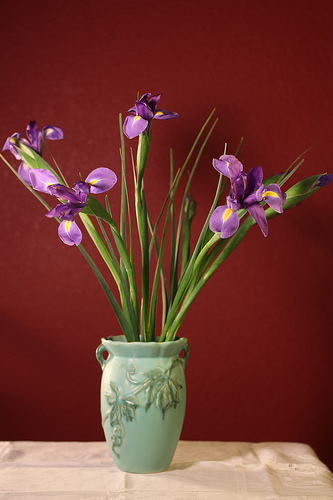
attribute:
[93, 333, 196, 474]
vase — green, light green, porcelain, decorative, blue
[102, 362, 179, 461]
design — leaf, leaves, green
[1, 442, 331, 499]
table cloth — tan, brown, white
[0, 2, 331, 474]
wall — red, burgundy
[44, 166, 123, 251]
flower bloom — purple, fully bloomed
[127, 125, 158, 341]
flower stem — green, long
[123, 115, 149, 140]
flower petal — purple, yellow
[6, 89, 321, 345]
bouquet — purple flowers, of flowers, of purple flowers, on display, flowers, purple, yellow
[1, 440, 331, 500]
table — white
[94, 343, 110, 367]
handle — green, small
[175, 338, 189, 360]
handle — small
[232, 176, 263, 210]
flower bud — purple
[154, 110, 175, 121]
flower petal — purple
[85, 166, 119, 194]
flower petal — purple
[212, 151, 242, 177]
flower petal — purple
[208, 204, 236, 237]
flower petal — purple